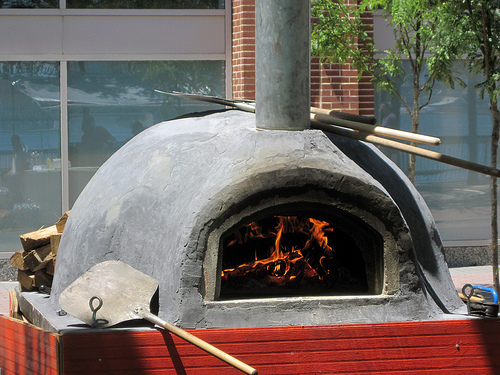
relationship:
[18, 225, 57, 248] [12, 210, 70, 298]
log of firewood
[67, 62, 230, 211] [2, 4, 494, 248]
window of building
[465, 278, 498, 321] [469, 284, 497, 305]
iron has handle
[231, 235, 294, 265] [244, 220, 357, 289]
wood in fire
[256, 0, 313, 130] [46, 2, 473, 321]
pipe on top of oven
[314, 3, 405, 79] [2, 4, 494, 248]
leaves in front of building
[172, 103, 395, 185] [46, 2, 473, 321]
top of oven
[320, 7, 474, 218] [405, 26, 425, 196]
tree has trunk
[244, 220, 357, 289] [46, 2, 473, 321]
fire in oven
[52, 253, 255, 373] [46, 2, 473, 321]
spatula next to oven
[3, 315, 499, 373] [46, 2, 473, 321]
bottom of oven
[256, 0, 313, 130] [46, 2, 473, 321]
pipe above oven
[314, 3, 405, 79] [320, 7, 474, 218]
leaves on tree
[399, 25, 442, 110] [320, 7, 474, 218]
branches on tree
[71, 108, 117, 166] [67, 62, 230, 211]
reflection in window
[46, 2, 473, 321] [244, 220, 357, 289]
oven has fire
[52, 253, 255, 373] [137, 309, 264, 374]
spatula has handle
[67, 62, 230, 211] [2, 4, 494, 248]
window in building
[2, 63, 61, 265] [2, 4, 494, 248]
window in building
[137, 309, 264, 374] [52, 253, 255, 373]
handle of spatula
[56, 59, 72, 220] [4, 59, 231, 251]
bar separating windows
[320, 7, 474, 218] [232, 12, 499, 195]
tree in background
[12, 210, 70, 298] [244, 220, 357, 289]
firewood for fire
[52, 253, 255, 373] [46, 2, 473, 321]
spatula for oven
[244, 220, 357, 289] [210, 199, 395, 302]
fire in hole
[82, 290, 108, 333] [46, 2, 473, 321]
handle on oven